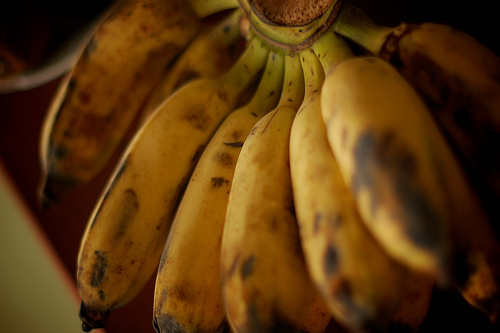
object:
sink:
[1, 0, 95, 91]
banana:
[320, 56, 473, 282]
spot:
[344, 117, 456, 269]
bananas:
[38, 2, 499, 333]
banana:
[75, 79, 251, 333]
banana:
[288, 99, 430, 333]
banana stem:
[251, 56, 285, 108]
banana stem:
[225, 37, 268, 94]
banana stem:
[279, 54, 301, 109]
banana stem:
[299, 48, 323, 96]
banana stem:
[308, 35, 348, 70]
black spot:
[75, 89, 93, 104]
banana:
[221, 98, 330, 333]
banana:
[288, 76, 431, 333]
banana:
[152, 104, 273, 333]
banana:
[376, 23, 500, 172]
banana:
[38, 0, 201, 202]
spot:
[303, 224, 357, 293]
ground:
[364, 177, 411, 207]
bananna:
[192, 0, 405, 112]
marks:
[300, 212, 369, 305]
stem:
[234, 0, 339, 48]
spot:
[351, 126, 438, 235]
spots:
[334, 122, 458, 252]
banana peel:
[383, 101, 434, 241]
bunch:
[40, 0, 500, 333]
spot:
[367, 133, 430, 223]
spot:
[304, 256, 375, 319]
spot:
[342, 135, 453, 252]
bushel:
[182, 0, 415, 109]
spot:
[327, 127, 438, 237]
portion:
[77, 77, 265, 333]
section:
[0, 0, 155, 333]